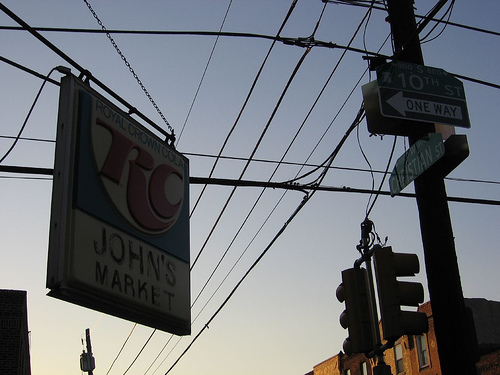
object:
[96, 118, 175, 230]
letter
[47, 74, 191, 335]
sign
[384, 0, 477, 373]
pole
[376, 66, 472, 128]
sign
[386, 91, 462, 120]
arrow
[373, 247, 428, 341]
traffic lights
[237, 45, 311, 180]
power lines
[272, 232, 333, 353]
cloud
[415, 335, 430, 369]
window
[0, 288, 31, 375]
wall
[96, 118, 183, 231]
rc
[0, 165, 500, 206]
wire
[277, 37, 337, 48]
transformer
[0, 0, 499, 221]
sky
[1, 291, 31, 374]
building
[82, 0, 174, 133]
chain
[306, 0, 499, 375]
side